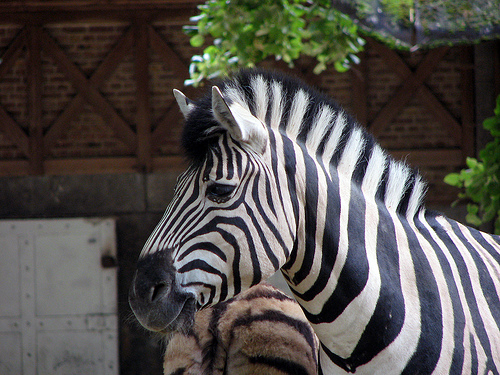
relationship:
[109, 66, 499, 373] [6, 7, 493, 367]
zebra standing outside of building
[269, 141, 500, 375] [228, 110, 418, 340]
stripe of zebra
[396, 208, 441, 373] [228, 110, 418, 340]
stripe of zebra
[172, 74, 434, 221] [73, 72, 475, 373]
mane of zebra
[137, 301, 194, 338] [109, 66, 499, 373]
mouth of zebra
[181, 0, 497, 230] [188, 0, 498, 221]
leaves in trees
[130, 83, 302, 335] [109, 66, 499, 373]
head of a zebra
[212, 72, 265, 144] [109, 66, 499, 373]
ear of a zebra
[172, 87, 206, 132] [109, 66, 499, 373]
ear of a zebra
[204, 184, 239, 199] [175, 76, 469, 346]
eye of a zebra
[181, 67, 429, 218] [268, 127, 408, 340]
hair running along neck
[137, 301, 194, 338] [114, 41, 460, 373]
mouth of a zebra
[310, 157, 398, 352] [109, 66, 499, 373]
neck of a zebra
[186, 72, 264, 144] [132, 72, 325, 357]
ear sticking out of head